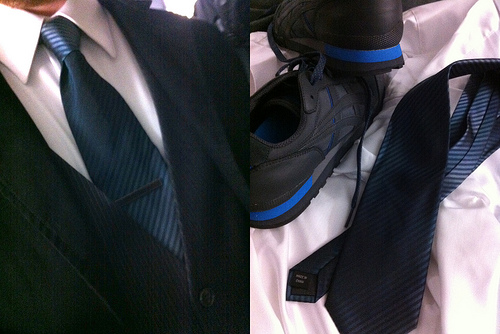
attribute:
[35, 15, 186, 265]
tie — blue, striped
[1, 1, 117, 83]
collar — white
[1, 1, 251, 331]
coat — black, striped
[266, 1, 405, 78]
shoe — blue, black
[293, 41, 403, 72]
heel — blue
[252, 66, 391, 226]
shoe — blue, black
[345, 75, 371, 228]
lace — black, thin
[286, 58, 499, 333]
tie — striped, black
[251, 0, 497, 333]
cloth — white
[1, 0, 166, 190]
shirt — bright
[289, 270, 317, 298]
tip — black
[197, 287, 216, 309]
button — small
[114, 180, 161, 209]
tie clip — black